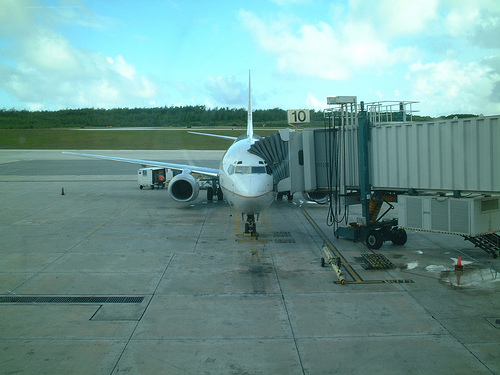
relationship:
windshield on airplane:
[227, 164, 270, 176] [60, 67, 281, 236]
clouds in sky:
[394, 9, 465, 80] [70, 22, 251, 92]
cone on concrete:
[50, 152, 85, 228] [37, 195, 220, 368]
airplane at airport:
[60, 67, 281, 236] [42, 45, 438, 367]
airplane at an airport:
[60, 67, 281, 236] [0, 97, 499, 373]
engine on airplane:
[167, 172, 198, 200] [74, 70, 291, 234]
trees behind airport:
[1, 105, 496, 127] [0, 127, 499, 373]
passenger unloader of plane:
[247, 112, 498, 259] [57, 69, 280, 245]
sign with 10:
[287, 106, 312, 123] [292, 108, 305, 120]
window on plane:
[227, 161, 272, 177] [57, 69, 280, 245]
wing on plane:
[60, 145, 220, 177] [61, 65, 290, 240]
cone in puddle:
[453, 250, 463, 267] [440, 262, 499, 294]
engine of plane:
[165, 161, 208, 208] [86, 84, 366, 294]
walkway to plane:
[269, 117, 498, 202] [58, 62, 326, 242]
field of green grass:
[46, 127, 185, 154] [62, 134, 95, 145]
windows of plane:
[230, 165, 272, 176] [71, 110, 371, 266]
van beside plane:
[124, 153, 226, 207] [136, 103, 368, 224]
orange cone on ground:
[453, 254, 464, 274] [19, 119, 483, 361]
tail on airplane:
[247, 70, 252, 142] [57, 69, 299, 237]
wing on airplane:
[46, 107, 220, 213] [33, 67, 337, 242]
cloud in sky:
[6, 7, 161, 107] [0, 4, 499, 119]